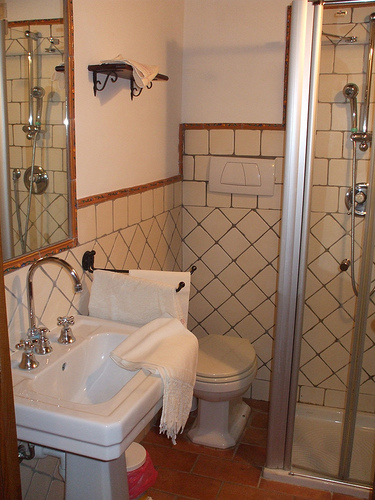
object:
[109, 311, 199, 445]
towel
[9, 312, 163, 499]
sink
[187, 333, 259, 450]
toilet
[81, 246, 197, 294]
towel rack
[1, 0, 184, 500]
wall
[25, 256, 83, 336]
faucet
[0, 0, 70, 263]
mirror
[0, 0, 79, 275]
frame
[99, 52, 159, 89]
towel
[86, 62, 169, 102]
shelf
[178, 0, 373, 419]
walls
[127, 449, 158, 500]
bag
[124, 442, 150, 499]
trashcan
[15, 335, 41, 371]
knob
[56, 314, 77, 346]
knob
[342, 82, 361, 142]
shower head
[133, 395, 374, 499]
floor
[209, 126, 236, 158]
tiles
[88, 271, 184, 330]
towel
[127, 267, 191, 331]
towel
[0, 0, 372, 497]
bathroom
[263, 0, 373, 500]
shower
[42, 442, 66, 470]
pipes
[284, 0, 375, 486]
doors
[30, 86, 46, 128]
shower head